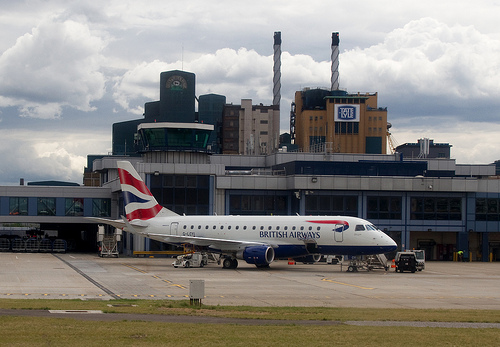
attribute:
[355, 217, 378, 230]
windshield — in front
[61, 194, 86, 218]
window — large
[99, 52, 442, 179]
building — dark colored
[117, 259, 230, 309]
marking — yellow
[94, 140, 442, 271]
airplane — white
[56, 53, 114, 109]
sky — gloomy, overcast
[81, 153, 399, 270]
plane — mid-sized, passenger plane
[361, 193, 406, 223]
window — large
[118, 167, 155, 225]
design — red and blue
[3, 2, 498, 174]
sky — gray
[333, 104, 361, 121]
logo — blue and white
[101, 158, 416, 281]
jet — passenger, british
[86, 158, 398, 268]
airplane — white, parked